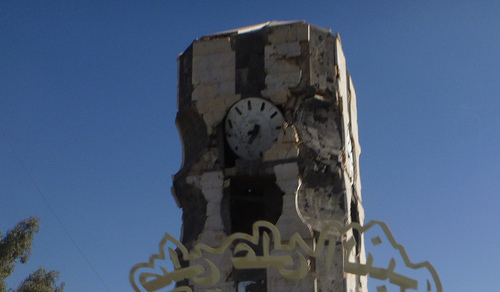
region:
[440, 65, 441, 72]
part of the sky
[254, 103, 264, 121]
part of a clock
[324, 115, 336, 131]
top of a wall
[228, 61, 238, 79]
part of a building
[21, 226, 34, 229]
tip of a tree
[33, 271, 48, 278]
leaves of a tree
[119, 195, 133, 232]
part of the sky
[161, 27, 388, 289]
A small clock tower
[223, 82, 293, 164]
clock on the clock tower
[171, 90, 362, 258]
damage on the tower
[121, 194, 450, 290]
arabic writing on a gate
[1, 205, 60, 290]
the tops of some trees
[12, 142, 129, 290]
some electrical wire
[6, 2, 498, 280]
a clear, blue sky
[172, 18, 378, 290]
a damaged stone tower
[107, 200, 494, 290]
a metal sign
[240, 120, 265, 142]
the hands of the clock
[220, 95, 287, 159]
black and white clock in tower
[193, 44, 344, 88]
black and white clock tower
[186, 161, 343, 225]
black and white clock tower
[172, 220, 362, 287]
black and white clock tower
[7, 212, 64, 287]
green leaves on tree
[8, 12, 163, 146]
blue sky with no clouds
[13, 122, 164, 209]
blue sky with no clouds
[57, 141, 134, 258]
blue sky with no clouds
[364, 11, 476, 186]
blue sky with no clouds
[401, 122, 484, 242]
blue sky with no clouds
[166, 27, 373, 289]
a stone clock tower with a clock.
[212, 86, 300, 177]
a clock on the front of a tower.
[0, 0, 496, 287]
a crystal clear blue sky.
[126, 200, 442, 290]
a metal object in front of a tower.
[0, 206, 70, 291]
a lush green leafy tree.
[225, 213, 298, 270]
a section of an iron fence.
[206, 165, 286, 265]
an arch on a clock tower.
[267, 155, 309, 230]
a stone pillar.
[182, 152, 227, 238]
a large stone pillar.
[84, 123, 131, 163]
a section of blue sky.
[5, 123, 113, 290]
clear blue sky with wire stretched across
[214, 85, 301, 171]
white clock set in stone base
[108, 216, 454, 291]
beige patterned metal work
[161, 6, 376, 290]
high stone tower with clock in middle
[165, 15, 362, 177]
light and dark stone tower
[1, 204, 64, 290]
two green trees with blue sky in background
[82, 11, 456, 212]
clock tower with clear blue sky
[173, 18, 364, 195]
stone tower with crumbling edge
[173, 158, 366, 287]
stone tower with light indented columns in front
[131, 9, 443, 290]
high stone tower with detailed metalwork in front